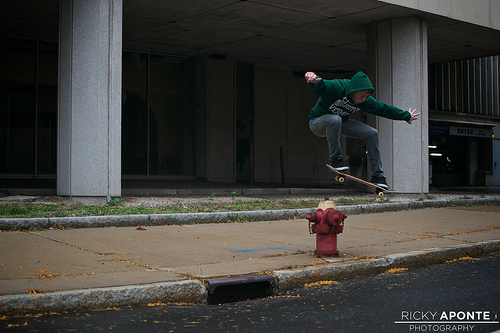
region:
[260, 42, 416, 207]
boy riding a skateboard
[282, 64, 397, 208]
boy doing a trick n skateboard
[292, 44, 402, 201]
boy wearing green hooded sweatshirt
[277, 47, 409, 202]
boy jumping over fire hydrant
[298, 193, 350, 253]
red fire hydrant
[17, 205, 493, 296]
ground is wet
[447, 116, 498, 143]
sign in front of parking garage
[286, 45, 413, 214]
boy wearing gray pants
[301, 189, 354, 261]
fire hydrant has yellow at the top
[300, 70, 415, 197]
A kid riding a skateboard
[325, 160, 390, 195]
A kid's wood skateboard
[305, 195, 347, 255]
A red fire hydrant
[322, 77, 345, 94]
A kid's right arm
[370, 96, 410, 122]
A kid's left arm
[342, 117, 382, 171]
A kid's left leg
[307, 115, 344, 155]
A kid's right leg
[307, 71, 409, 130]
A kid's hooded sweatshirt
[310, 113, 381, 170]
A kid's denim jeans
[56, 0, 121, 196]
a grey concrete pillar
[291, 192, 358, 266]
red and yellow fire hydrant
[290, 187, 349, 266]
chains on the fire hydrant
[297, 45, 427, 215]
kid on a skateboard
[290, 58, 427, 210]
skateboarder is wearing a green hoodie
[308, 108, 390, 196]
skateboarder is wearing black skinny jeans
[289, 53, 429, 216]
skateboarder has his arms out for balance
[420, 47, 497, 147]
metal railing off to the left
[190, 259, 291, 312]
storm drain in the road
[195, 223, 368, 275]
blue spray painted line on the sidewalk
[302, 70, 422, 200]
A kid on a skateboard.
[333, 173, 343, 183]
The wheels on the skateboard.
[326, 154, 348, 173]
The boy's black shoe.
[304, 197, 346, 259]
A red fire hydrant.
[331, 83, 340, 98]
Part of the green sweatshirt.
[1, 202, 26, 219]
A patch of green grass.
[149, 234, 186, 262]
Part of the sidewalk.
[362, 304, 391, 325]
Part of the road.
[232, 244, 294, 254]
A blue line on the sidewalk.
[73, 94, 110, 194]
Part of a grey pillar.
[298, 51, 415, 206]
a boy jumping with a skateboard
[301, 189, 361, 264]
a red fire hydrant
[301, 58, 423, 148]
a green hoodie on a boy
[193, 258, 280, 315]
a metal storm drain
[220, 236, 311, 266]
blue paint on the sidewalk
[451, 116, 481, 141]
a blue enter sign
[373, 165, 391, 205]
a black and white skateboard shoe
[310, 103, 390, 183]
grey jeans on a boy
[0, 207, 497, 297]
a cement sidewalk